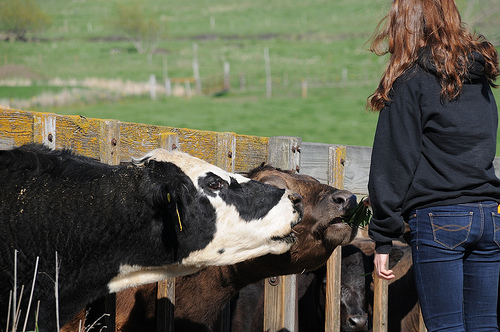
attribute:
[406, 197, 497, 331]
jeans — blue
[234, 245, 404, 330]
cow — black, dark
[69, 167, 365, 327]
cow — brown, dark, eating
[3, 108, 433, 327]
pen — wood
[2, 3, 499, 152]
grass — green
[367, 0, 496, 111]
hair — brown, long, messy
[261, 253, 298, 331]
pole — wood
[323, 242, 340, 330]
pole — wood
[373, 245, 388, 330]
pole — wood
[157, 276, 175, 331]
pole — wood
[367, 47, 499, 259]
sweatshirt — dark, long sleeved, black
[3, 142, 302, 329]
cow — black, white, fluffy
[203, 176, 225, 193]
eye — brown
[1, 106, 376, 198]
fence — painted, yellow, wooden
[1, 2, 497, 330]
photo — clear